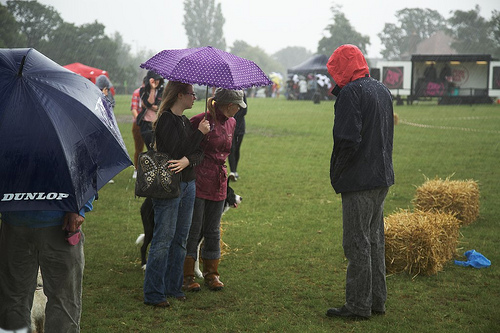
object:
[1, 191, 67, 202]
logo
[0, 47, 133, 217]
umbrella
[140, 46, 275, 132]
umbrella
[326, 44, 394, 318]
person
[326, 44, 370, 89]
hood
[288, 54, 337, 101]
tent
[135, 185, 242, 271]
dog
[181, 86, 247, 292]
woman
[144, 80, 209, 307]
woman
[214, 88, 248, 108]
cap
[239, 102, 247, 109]
visor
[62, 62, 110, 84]
tent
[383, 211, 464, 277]
hay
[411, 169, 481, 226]
bale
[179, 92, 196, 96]
eyeglasses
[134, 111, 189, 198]
handbag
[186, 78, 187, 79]
polka dot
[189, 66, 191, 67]
polka dot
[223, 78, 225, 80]
polka dot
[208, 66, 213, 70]
polka dot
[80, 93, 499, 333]
field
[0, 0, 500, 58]
sky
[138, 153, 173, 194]
butterfly design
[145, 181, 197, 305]
jeans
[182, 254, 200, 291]
boot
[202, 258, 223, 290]
boot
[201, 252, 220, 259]
trim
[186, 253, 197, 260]
trim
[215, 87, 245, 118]
head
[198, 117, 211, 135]
hand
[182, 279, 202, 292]
foot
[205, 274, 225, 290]
foot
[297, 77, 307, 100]
person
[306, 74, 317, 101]
person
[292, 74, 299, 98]
person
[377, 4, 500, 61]
trees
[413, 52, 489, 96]
stage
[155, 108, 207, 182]
top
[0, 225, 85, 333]
jeans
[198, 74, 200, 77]
polka dot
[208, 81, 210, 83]
polka dot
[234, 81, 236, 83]
polka dot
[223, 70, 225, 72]
polka dot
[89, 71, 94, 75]
dot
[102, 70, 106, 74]
dot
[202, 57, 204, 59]
polka dot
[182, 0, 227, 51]
tree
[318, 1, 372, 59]
tree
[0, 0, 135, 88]
tree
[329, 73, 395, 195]
parka